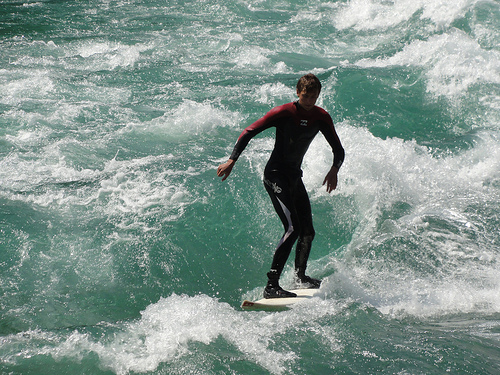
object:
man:
[215, 73, 346, 300]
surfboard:
[241, 279, 328, 312]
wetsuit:
[227, 103, 344, 286]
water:
[2, 0, 499, 375]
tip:
[238, 298, 255, 311]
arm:
[227, 108, 273, 166]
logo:
[299, 119, 308, 127]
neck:
[292, 100, 321, 113]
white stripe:
[276, 196, 295, 248]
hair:
[296, 73, 323, 95]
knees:
[284, 224, 304, 239]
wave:
[119, 287, 247, 362]